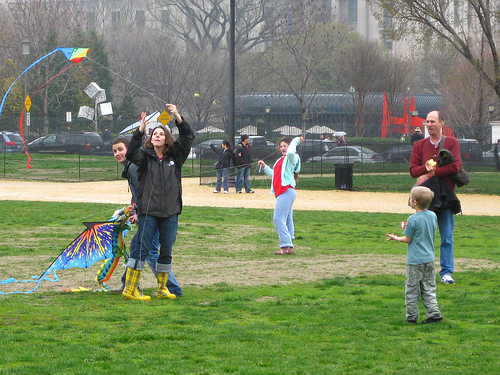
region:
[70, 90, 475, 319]
People at the field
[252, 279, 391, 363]
Grass on the field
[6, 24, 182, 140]
A kite in the air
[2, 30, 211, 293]
A woman flying a kite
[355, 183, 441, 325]
A boy holding a kite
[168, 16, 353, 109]
Trees growing in the background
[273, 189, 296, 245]
Blue pants in the photo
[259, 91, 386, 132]
A house in the background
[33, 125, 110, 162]
A black car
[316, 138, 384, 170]
A gray car on the road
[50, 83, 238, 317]
children with kites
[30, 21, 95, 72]
kite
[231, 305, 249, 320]
short green and yellow grass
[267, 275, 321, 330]
short green and yellow grass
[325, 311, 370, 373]
short green and yellow grass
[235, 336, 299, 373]
short green and yellow grass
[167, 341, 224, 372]
short green and yellow grass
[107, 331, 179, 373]
short green and yellow grass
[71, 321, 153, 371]
short green and yellow grass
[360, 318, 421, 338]
short green and yellow grass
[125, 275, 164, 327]
This woman is wearing yellow boots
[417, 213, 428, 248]
This child is wearing a blue t-shirt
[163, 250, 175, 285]
This woman is wearing a pair of jeans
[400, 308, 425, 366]
This child is wearing khaki pants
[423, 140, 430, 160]
This man is wearing a red shirt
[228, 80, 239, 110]
There is a black pole here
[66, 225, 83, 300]
There is a multi-colored kite here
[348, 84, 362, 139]
There is a black train car here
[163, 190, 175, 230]
This lady is wearing a black jacket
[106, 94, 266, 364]
Jackson Mingus took this photo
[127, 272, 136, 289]
yellow boot on woman.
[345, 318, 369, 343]
grass on the ground.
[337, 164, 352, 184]
trash bin on grass.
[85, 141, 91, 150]
taillight on the vehicle.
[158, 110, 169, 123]
sign on the post.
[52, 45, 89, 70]
kite on the string.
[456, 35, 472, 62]
branch of the tree.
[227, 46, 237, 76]
pole in the park.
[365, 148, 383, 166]
fence along the grass.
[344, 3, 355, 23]
window on the building.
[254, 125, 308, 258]
girl wearing blue coat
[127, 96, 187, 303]
woman wearing yellow boots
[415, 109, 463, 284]
man holding black coat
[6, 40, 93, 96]
kite flying in the air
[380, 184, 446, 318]
young boy wearing gray pants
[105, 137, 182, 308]
young man holding a kite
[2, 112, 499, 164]
cars in the parking lot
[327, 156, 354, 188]
black trashcan in the grass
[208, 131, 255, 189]
people walking on the dirt path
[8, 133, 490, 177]
black fencing